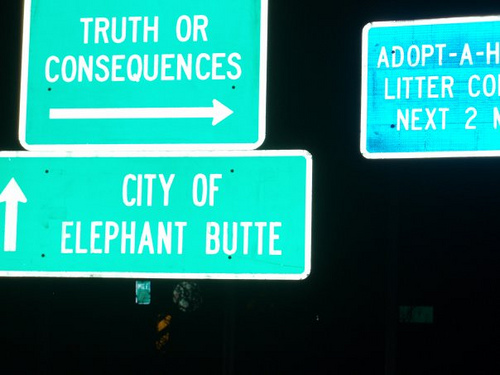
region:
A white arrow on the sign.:
[46, 95, 238, 151]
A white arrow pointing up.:
[3, 173, 30, 254]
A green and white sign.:
[2, 157, 334, 280]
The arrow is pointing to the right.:
[58, 84, 235, 139]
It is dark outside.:
[268, 43, 456, 337]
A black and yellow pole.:
[135, 303, 179, 365]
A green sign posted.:
[335, 25, 487, 185]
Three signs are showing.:
[28, 23, 464, 251]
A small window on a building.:
[120, 260, 162, 305]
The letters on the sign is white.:
[64, 16, 247, 101]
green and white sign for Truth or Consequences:
[19, 0, 265, 148]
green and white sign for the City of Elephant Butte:
[1, 150, 312, 281]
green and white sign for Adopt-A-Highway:
[358, 15, 498, 160]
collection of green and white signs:
[0, 2, 499, 279]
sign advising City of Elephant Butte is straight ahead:
[0, 150, 312, 282]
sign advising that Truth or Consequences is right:
[17, 0, 266, 150]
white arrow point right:
[47, 98, 232, 127]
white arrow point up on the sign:
[0, 175, 29, 252]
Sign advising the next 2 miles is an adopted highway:
[359, 20, 499, 158]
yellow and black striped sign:
[155, 313, 173, 353]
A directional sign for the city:
[1, 154, 307, 271]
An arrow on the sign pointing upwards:
[1, 169, 26, 249]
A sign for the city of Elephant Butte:
[0, 158, 308, 280]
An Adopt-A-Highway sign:
[363, 24, 498, 155]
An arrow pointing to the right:
[43, 98, 231, 128]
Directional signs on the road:
[0, 3, 313, 284]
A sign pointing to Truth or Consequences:
[27, 3, 261, 144]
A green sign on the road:
[3, 155, 310, 276]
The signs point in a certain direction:
[3, 5, 309, 273]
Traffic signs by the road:
[3, 2, 310, 277]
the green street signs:
[0, 1, 499, 276]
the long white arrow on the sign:
[48, 100, 233, 127]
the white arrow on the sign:
[2, 176, 25, 249]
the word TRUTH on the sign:
[80, 17, 158, 43]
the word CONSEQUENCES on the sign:
[44, 53, 241, 83]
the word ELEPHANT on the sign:
[61, 219, 186, 254]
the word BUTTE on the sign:
[206, 220, 283, 254]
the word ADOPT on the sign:
[376, 44, 446, 69]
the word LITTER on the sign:
[383, 75, 453, 99]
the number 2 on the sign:
[464, 106, 476, 129]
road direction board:
[23, 11, 298, 276]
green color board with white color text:
[20, 7, 297, 267]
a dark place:
[326, 163, 456, 348]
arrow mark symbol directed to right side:
[43, 93, 238, 135]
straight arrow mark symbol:
[2, 173, 36, 268]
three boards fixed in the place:
[7, 0, 478, 339]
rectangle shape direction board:
[2, 143, 329, 299]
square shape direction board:
[21, 8, 283, 150]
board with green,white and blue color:
[365, 24, 499, 156]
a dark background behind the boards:
[19, 20, 486, 346]